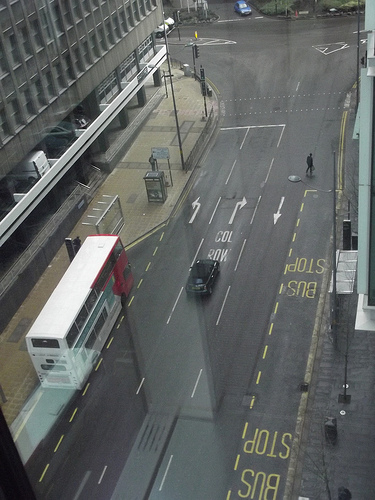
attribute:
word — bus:
[288, 282, 317, 300]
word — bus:
[236, 467, 279, 498]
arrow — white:
[188, 196, 200, 223]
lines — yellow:
[211, 177, 316, 486]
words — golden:
[265, 226, 333, 307]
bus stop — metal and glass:
[93, 193, 126, 239]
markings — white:
[215, 285, 232, 324]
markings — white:
[231, 237, 246, 269]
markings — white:
[247, 196, 262, 223]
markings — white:
[264, 158, 274, 181]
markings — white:
[190, 366, 202, 401]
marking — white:
[218, 122, 288, 147]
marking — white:
[259, 156, 275, 188]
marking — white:
[221, 157, 238, 184]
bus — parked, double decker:
[24, 235, 135, 392]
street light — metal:
[156, 12, 196, 178]